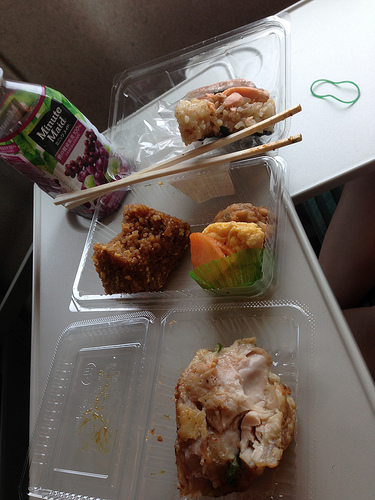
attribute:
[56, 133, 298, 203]
chopstick — wood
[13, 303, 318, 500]
plastic — clear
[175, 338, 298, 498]
meat — half eaten, missing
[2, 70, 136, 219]
bottle — grape juice, juice, plastic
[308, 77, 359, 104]
band — green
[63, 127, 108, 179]
grapes — purple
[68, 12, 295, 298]
box — plastic, open, clear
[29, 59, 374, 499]
tray — white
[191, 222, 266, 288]
food — wrapped, orange